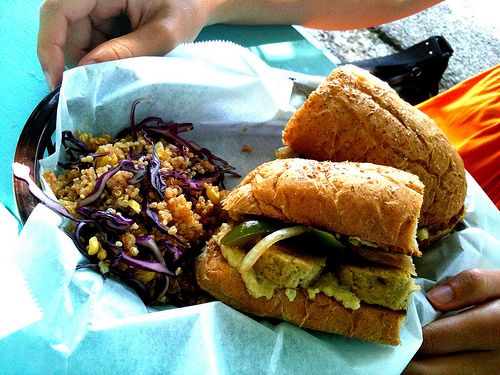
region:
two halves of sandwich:
[204, 65, 460, 339]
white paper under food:
[154, 46, 280, 163]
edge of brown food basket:
[13, 95, 54, 210]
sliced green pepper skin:
[218, 219, 268, 249]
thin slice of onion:
[238, 226, 295, 271]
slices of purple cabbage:
[103, 156, 160, 190]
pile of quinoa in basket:
[66, 133, 218, 268]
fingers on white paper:
[415, 271, 498, 373]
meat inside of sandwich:
[258, 251, 410, 311]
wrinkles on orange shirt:
[453, 72, 497, 159]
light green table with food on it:
[0, 0, 496, 370]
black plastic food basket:
[8, 52, 496, 348]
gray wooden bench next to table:
[253, 0, 498, 237]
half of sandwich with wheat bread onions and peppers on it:
[189, 151, 431, 351]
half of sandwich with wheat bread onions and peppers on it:
[276, 58, 471, 260]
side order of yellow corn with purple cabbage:
[38, 96, 261, 312]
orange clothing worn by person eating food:
[366, 24, 498, 233]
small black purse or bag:
[321, 31, 458, 141]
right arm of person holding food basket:
[21, 0, 486, 110]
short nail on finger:
[426, 284, 459, 306]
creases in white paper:
[181, 306, 251, 349]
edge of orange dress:
[444, 92, 485, 139]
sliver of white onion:
[246, 227, 302, 277]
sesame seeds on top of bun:
[358, 102, 415, 150]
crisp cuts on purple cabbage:
[80, 190, 132, 239]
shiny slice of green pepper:
[215, 220, 260, 244]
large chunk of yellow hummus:
[301, 252, 420, 305]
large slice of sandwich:
[204, 151, 430, 339]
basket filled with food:
[60, 59, 466, 351]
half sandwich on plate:
[211, 170, 411, 337]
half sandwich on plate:
[296, 89, 479, 206]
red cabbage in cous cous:
[121, 253, 153, 274]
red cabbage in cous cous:
[92, 166, 126, 190]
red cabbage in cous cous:
[81, 214, 129, 234]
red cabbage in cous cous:
[181, 174, 210, 189]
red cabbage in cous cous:
[132, 113, 177, 142]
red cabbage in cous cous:
[146, 268, 173, 302]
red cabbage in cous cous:
[63, 223, 93, 243]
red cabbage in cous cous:
[159, 225, 188, 250]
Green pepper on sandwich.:
[241, 211, 309, 244]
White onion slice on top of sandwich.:
[244, 216, 306, 265]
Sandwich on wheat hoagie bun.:
[251, 148, 469, 373]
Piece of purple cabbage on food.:
[103, 243, 171, 283]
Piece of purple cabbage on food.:
[88, 205, 148, 225]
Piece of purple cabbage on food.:
[129, 143, 174, 205]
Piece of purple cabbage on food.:
[116, 108, 168, 142]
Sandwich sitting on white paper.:
[184, 270, 401, 362]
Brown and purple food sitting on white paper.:
[73, 119, 197, 317]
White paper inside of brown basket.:
[11, 130, 113, 277]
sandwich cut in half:
[194, 150, 428, 352]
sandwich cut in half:
[277, 57, 464, 241]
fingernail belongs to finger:
[426, 276, 456, 309]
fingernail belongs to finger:
[40, 72, 55, 92]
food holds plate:
[11, 57, 456, 345]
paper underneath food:
[3, 40, 498, 375]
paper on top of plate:
[0, 42, 499, 374]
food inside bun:
[221, 217, 411, 317]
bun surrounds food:
[191, 150, 424, 352]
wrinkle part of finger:
[104, 44, 121, 61]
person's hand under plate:
[406, 268, 499, 373]